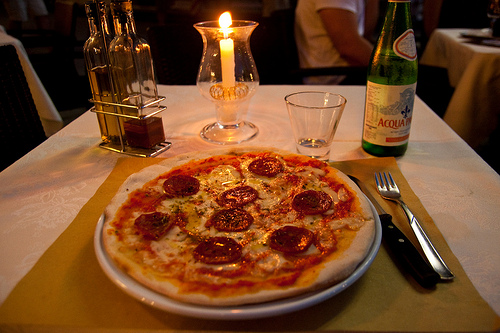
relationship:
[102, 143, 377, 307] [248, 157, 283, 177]
pizza has pepperoni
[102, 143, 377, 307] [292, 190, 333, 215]
pizza has pepperoni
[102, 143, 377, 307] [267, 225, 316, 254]
pizza has pepperoni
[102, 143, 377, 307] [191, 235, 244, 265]
pizza has pepperoni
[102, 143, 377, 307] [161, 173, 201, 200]
pizza has pepperoni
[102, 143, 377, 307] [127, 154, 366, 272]
pizza has cheese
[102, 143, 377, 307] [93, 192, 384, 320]
pizza on top of plate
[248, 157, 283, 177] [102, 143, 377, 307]
pepperoni on top of pizza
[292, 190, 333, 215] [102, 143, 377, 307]
pepperoni on top of pizza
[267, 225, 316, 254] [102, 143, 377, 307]
pepperoni on top of pizza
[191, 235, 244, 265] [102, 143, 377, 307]
pepperoni on top of pizza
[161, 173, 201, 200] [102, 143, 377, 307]
pepperoni on top of pizza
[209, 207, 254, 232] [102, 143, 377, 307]
pepperoni on top of pizza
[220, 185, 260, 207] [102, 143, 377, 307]
pepperoni on top of pizza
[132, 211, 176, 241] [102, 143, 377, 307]
pepperoni on top of pizza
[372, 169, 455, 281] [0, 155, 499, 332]
fork on top of mat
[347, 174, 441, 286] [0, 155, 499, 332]
knife on top of mat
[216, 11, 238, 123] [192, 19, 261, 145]
candle in container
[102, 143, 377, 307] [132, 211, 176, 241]
pizza has pepperoni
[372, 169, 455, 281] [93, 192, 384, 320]
fork near plate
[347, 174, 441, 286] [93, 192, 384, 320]
knife near plate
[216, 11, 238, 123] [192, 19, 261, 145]
candle in glass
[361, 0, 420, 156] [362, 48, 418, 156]
bottle has water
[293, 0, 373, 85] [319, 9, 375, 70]
person has arm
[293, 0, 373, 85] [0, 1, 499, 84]
person in background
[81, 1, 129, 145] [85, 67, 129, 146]
container has oil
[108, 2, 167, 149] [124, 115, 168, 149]
container has vinegar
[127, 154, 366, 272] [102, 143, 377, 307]
cheese on top of pizza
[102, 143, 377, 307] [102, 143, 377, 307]
pizza has pizza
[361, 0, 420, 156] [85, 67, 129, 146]
bottle has oil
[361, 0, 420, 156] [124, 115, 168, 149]
bottle has vinegar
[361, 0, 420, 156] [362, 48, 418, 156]
bottle has wine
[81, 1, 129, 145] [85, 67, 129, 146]
carafe has oil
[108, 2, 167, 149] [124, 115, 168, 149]
carafe has vinegar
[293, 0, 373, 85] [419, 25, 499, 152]
person at table